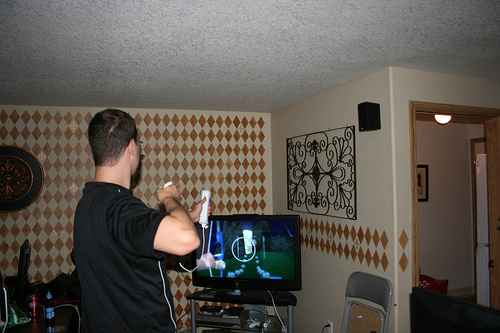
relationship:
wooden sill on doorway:
[404, 103, 499, 324] [388, 59, 498, 329]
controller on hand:
[198, 189, 211, 224] [187, 194, 209, 225]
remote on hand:
[156, 172, 186, 206] [154, 180, 184, 204]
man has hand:
[69, 108, 214, 330] [187, 194, 209, 225]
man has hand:
[69, 108, 214, 330] [154, 180, 184, 204]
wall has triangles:
[181, 115, 271, 183] [195, 128, 217, 143]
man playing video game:
[69, 108, 214, 330] [192, 187, 277, 277]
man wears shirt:
[69, 108, 214, 330] [68, 179, 180, 331]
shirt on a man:
[72, 182, 183, 319] [69, 108, 214, 330]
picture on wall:
[388, 151, 469, 203] [270, 61, 406, 326]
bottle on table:
[34, 284, 68, 325] [4, 303, 46, 331]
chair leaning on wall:
[338, 270, 393, 331] [270, 61, 406, 326]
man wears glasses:
[69, 108, 214, 330] [136, 134, 146, 152]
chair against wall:
[338, 270, 393, 331] [266, 110, 412, 327]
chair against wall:
[319, 264, 406, 328] [257, 91, 394, 331]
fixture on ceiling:
[435, 114, 453, 125] [413, 107, 493, 124]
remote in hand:
[156, 172, 186, 206] [157, 190, 180, 200]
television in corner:
[187, 213, 303, 291] [261, 107, 283, 214]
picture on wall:
[412, 162, 430, 203] [415, 120, 475, 303]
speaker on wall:
[353, 100, 381, 132] [283, 112, 396, 283]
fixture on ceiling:
[435, 114, 453, 125] [415, 104, 480, 131]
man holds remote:
[69, 108, 214, 330] [195, 187, 215, 229]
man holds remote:
[69, 108, 214, 330] [155, 175, 183, 201]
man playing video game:
[69, 108, 214, 330] [192, 220, 294, 279]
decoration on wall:
[281, 127, 364, 214] [195, 110, 272, 200]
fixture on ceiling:
[435, 114, 453, 125] [4, 2, 495, 113]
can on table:
[26, 298, 41, 318] [5, 304, 67, 327]